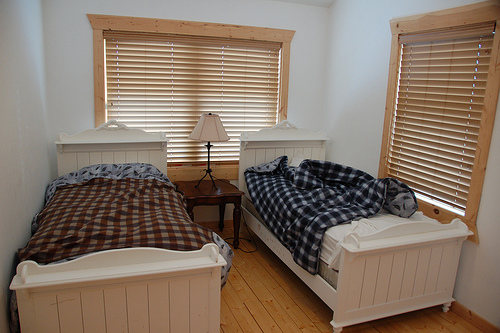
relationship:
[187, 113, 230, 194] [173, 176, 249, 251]
lamp on stand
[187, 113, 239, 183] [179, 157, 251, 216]
lamp on table